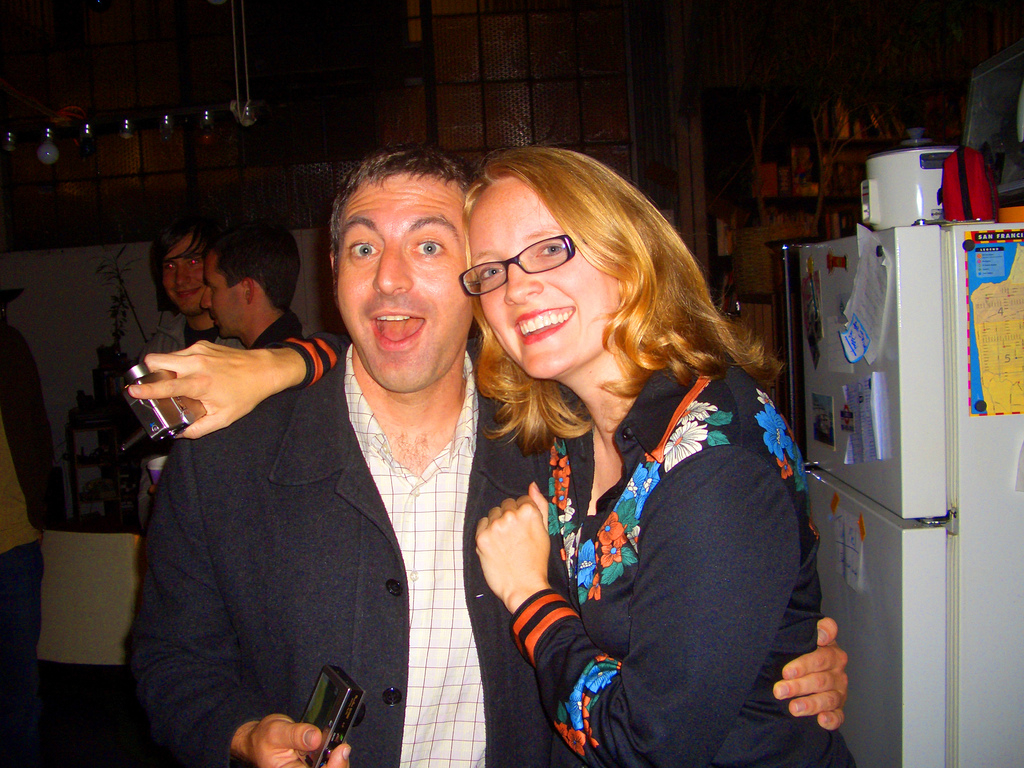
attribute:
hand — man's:
[242, 707, 347, 766]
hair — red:
[453, 145, 779, 444]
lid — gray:
[863, 121, 956, 156]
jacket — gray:
[134, 351, 575, 764]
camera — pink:
[123, 338, 229, 475]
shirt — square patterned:
[321, 340, 522, 760]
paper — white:
[832, 361, 893, 466]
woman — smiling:
[458, 140, 866, 755]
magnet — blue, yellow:
[952, 220, 1022, 437]